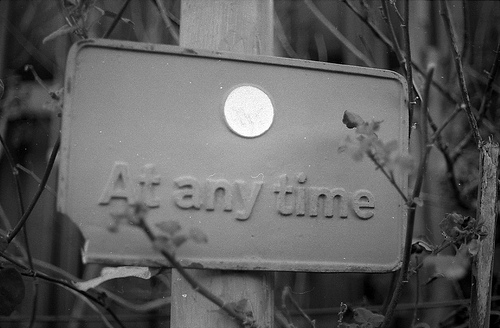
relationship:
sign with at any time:
[62, 45, 448, 291] [97, 162, 378, 221]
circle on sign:
[220, 84, 285, 143] [62, 45, 448, 291]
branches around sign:
[373, 22, 493, 242] [62, 45, 448, 291]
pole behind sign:
[181, 4, 287, 57] [62, 45, 448, 291]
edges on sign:
[59, 37, 76, 130] [62, 45, 448, 291]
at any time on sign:
[97, 162, 378, 221] [62, 45, 448, 291]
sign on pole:
[62, 45, 448, 291] [181, 4, 287, 57]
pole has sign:
[181, 4, 287, 57] [62, 45, 448, 291]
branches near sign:
[373, 22, 493, 242] [62, 45, 448, 291]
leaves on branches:
[432, 214, 488, 245] [373, 22, 493, 242]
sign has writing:
[62, 45, 448, 291] [162, 179, 431, 220]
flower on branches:
[413, 219, 493, 263] [373, 22, 493, 242]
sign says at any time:
[62, 45, 448, 291] [105, 165, 386, 234]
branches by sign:
[373, 22, 493, 242] [62, 45, 448, 291]